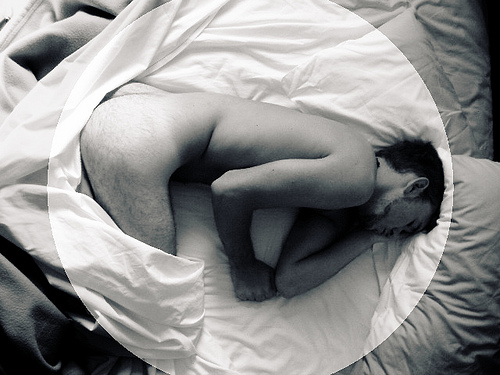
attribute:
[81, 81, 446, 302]
man — dead, sleeping, naked, laying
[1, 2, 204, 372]
sheet — white